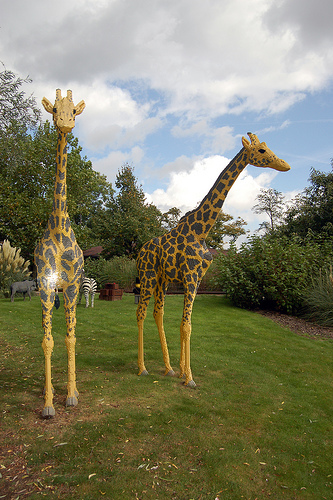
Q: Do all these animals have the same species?
A: No, there are both giraffes and zebras.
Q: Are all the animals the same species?
A: No, there are both giraffes and zebras.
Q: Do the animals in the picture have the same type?
A: No, they are giraffes and zebras.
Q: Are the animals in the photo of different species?
A: Yes, they are giraffes and zebras.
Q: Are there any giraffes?
A: Yes, there is a giraffe.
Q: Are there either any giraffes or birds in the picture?
A: Yes, there is a giraffe.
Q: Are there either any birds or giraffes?
A: Yes, there is a giraffe.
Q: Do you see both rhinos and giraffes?
A: No, there is a giraffe but no rhinos.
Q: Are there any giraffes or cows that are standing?
A: Yes, the giraffe is standing.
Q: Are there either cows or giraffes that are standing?
A: Yes, the giraffe is standing.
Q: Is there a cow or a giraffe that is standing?
A: Yes, the giraffe is standing.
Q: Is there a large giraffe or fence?
A: Yes, there is a large giraffe.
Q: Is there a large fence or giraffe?
A: Yes, there is a large giraffe.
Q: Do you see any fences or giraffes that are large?
A: Yes, the giraffe is large.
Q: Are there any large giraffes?
A: Yes, there is a large giraffe.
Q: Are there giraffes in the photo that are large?
A: Yes, there is a giraffe that is large.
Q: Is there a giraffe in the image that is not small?
A: Yes, there is a large giraffe.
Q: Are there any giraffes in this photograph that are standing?
A: Yes, there is a giraffe that is standing.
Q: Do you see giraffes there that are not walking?
A: Yes, there is a giraffe that is standing .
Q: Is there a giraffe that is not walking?
A: Yes, there is a giraffe that is standing.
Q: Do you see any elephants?
A: No, there are no elephants.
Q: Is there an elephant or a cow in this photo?
A: No, there are no elephants or cows.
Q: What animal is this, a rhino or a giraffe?
A: This is a giraffe.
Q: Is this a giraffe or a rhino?
A: This is a giraffe.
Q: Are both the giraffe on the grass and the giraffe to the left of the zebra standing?
A: Yes, both the giraffe and the giraffe are standing.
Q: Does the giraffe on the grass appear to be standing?
A: Yes, the giraffe is standing.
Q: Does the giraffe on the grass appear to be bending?
A: No, the giraffe is standing.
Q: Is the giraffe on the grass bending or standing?
A: The giraffe is standing.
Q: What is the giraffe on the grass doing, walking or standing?
A: The giraffe is standing.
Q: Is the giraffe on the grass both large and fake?
A: Yes, the giraffe is large and fake.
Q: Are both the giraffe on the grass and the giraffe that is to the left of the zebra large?
A: Yes, both the giraffe and the giraffe are large.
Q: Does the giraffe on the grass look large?
A: Yes, the giraffe is large.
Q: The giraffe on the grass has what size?
A: The giraffe is large.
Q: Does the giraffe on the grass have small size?
A: No, the giraffe is large.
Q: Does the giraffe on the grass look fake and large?
A: Yes, the giraffe is fake and large.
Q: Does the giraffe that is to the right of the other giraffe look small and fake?
A: No, the giraffe is fake but large.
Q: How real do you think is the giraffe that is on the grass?
A: The giraffe is fake.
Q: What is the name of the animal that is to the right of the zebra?
A: The animal is a giraffe.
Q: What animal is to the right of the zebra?
A: The animal is a giraffe.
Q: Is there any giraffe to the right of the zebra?
A: Yes, there is a giraffe to the right of the zebra.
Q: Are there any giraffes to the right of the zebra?
A: Yes, there is a giraffe to the right of the zebra.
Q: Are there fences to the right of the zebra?
A: No, there is a giraffe to the right of the zebra.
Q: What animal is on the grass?
A: The giraffe is on the grass.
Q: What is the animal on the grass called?
A: The animal is a giraffe.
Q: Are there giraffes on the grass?
A: Yes, there is a giraffe on the grass.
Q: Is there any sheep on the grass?
A: No, there is a giraffe on the grass.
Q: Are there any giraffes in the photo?
A: Yes, there is a giraffe.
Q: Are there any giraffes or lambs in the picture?
A: Yes, there is a giraffe.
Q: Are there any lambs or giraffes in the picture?
A: Yes, there is a giraffe.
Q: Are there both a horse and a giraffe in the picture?
A: No, there is a giraffe but no horses.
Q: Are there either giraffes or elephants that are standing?
A: Yes, the giraffe is standing.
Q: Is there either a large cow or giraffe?
A: Yes, there is a large giraffe.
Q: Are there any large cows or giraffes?
A: Yes, there is a large giraffe.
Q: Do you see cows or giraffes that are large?
A: Yes, the giraffe is large.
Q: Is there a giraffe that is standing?
A: Yes, there is a giraffe that is standing.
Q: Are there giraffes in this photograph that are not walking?
A: Yes, there is a giraffe that is standing.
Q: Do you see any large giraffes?
A: Yes, there is a large giraffe.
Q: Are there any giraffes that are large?
A: Yes, there is a giraffe that is large.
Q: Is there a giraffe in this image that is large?
A: Yes, there is a giraffe that is large.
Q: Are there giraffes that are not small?
A: Yes, there is a large giraffe.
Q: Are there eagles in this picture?
A: No, there are no eagles.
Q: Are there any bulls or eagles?
A: No, there are no eagles or bulls.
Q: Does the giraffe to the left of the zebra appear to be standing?
A: Yes, the giraffe is standing.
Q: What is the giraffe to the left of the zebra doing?
A: The giraffe is standing.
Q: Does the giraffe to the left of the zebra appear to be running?
A: No, the giraffe is standing.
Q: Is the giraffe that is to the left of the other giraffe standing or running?
A: The giraffe is standing.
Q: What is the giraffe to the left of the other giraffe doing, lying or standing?
A: The giraffe is standing.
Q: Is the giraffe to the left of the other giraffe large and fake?
A: Yes, the giraffe is large and fake.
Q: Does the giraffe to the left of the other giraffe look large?
A: Yes, the giraffe is large.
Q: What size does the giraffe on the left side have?
A: The giraffe has large size.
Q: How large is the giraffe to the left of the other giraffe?
A: The giraffe is large.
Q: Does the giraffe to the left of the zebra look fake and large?
A: Yes, the giraffe is fake and large.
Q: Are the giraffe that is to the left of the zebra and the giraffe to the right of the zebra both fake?
A: Yes, both the giraffe and the giraffe are fake.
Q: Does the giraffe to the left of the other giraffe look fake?
A: Yes, the giraffe is fake.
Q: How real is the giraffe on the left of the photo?
A: The giraffe is fake.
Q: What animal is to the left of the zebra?
A: The animal is a giraffe.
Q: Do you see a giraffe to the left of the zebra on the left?
A: Yes, there is a giraffe to the left of the zebra.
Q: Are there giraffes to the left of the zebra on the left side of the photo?
A: Yes, there is a giraffe to the left of the zebra.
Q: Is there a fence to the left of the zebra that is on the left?
A: No, there is a giraffe to the left of the zebra.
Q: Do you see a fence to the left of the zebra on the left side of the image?
A: No, there is a giraffe to the left of the zebra.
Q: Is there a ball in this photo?
A: No, there are no balls.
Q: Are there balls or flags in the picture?
A: No, there are no balls or flags.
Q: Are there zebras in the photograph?
A: Yes, there is a zebra.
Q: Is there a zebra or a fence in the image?
A: Yes, there is a zebra.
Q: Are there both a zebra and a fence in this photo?
A: No, there is a zebra but no fences.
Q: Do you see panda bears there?
A: No, there are no panda bears.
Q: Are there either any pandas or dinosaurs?
A: No, there are no pandas or dinosaurs.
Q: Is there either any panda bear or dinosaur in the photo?
A: No, there are no pandas or dinosaurs.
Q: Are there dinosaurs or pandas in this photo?
A: No, there are no pandas or dinosaurs.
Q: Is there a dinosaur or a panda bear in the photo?
A: No, there are no pandas or dinosaurs.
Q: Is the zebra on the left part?
A: Yes, the zebra is on the left of the image.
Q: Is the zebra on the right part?
A: No, the zebra is on the left of the image.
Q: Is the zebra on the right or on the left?
A: The zebra is on the left of the image.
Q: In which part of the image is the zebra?
A: The zebra is on the left of the image.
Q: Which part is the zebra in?
A: The zebra is on the left of the image.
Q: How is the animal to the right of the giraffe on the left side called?
A: The animal is a zebra.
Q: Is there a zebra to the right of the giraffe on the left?
A: Yes, there is a zebra to the right of the giraffe.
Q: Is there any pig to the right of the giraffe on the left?
A: No, there is a zebra to the right of the giraffe.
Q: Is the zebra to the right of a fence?
A: No, the zebra is to the right of the giraffe.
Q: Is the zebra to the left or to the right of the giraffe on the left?
A: The zebra is to the right of the giraffe.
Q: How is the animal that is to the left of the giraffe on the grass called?
A: The animal is a zebra.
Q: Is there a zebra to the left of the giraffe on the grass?
A: Yes, there is a zebra to the left of the giraffe.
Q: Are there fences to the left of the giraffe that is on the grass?
A: No, there is a zebra to the left of the giraffe.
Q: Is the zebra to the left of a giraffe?
A: Yes, the zebra is to the left of a giraffe.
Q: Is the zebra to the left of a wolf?
A: No, the zebra is to the left of a giraffe.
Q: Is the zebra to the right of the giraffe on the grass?
A: No, the zebra is to the left of the giraffe.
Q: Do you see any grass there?
A: Yes, there is grass.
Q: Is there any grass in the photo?
A: Yes, there is grass.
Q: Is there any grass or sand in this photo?
A: Yes, there is grass.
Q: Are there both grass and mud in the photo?
A: No, there is grass but no mud.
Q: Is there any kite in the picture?
A: No, there are no kites.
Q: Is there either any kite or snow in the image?
A: No, there are no kites or snow.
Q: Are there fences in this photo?
A: No, there are no fences.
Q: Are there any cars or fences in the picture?
A: No, there are no fences or cars.